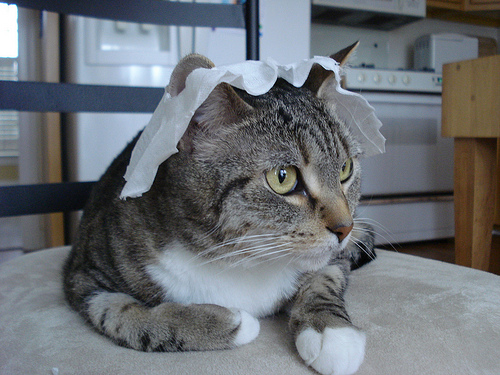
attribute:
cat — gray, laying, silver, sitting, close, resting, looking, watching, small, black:
[122, 101, 411, 357]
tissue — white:
[253, 51, 307, 93]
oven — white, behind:
[359, 65, 459, 182]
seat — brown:
[378, 267, 474, 339]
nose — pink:
[325, 212, 357, 244]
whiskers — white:
[193, 227, 296, 274]